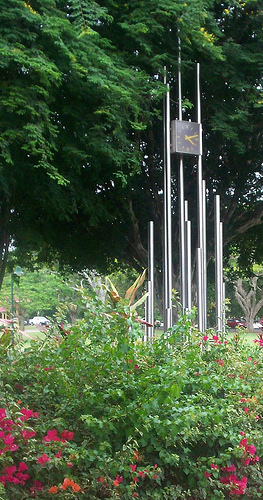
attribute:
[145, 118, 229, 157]
clock — high, blue, fixed, black, square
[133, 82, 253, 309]
poles — different, standing, silver, metal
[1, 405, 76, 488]
flowers — pink, red, orange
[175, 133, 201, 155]
hands — yellow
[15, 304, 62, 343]
truck — white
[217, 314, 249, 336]
car — red, white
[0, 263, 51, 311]
post — green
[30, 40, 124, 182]
leaves — green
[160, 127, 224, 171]
time — 4:13, 4:12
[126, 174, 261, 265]
woods — brown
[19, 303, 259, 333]
cars — parked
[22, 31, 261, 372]
tree — behind, daytime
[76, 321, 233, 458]
bush — large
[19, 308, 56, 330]
vehicle — distant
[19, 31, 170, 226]
tree — large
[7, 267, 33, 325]
light — green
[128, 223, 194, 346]
pipe — large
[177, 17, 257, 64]
flowers — yellow